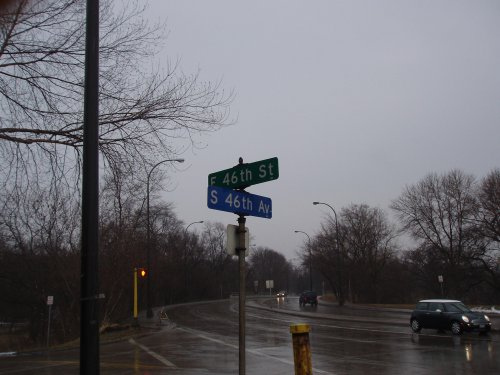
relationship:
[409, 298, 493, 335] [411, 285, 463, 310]
car with roof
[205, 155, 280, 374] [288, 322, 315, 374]
sign on pole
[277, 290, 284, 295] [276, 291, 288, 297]
lights on front of car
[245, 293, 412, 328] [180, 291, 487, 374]
medium in road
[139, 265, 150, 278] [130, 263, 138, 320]
lamp on pole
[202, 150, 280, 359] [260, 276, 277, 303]
sign on street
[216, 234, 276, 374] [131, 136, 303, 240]
pole has signs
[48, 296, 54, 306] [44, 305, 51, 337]
white sign on pole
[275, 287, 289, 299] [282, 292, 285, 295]
car has light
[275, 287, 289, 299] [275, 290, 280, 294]
car has light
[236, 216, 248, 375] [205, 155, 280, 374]
pole for sign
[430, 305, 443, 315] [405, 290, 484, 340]
mirror on vehicle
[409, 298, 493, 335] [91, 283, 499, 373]
car on road